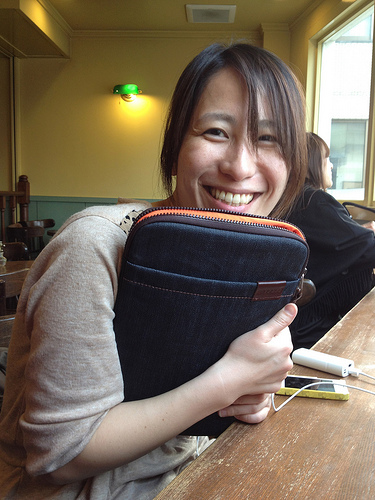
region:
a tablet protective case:
[120, 205, 310, 435]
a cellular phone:
[274, 374, 347, 399]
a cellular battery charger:
[292, 345, 355, 376]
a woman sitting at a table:
[2, 40, 307, 499]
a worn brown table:
[162, 285, 374, 497]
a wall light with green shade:
[109, 81, 140, 105]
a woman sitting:
[302, 130, 373, 287]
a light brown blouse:
[4, 200, 212, 499]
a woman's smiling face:
[159, 42, 303, 217]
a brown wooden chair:
[13, 213, 54, 252]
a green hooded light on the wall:
[108, 75, 142, 102]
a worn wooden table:
[161, 290, 372, 498]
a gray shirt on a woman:
[2, 196, 215, 498]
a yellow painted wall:
[0, 28, 315, 203]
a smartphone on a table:
[271, 370, 349, 400]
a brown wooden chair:
[4, 215, 60, 256]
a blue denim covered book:
[112, 207, 307, 407]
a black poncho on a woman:
[282, 183, 373, 312]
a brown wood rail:
[1, 167, 32, 233]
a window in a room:
[306, 1, 373, 208]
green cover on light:
[105, 79, 138, 97]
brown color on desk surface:
[252, 442, 339, 473]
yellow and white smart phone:
[291, 371, 355, 401]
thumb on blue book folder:
[250, 297, 300, 337]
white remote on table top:
[296, 342, 345, 373]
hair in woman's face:
[223, 50, 303, 156]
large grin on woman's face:
[194, 176, 274, 215]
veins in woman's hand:
[252, 348, 284, 384]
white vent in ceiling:
[168, 1, 261, 27]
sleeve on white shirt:
[27, 411, 102, 454]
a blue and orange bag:
[113, 200, 301, 435]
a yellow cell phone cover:
[276, 373, 352, 401]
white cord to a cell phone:
[272, 344, 374, 409]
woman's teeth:
[200, 179, 263, 215]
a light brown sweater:
[2, 191, 275, 497]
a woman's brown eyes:
[188, 116, 290, 151]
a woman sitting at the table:
[287, 133, 372, 284]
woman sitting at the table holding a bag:
[33, 46, 346, 497]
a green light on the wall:
[108, 76, 151, 109]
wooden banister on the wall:
[0, 171, 36, 227]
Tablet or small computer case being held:
[117, 199, 306, 430]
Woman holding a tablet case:
[18, 40, 300, 498]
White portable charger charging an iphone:
[263, 333, 373, 413]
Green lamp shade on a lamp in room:
[102, 76, 150, 112]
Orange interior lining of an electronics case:
[134, 208, 311, 234]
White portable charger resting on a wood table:
[289, 346, 360, 375]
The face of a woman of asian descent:
[139, 37, 316, 239]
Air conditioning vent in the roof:
[184, 3, 237, 25]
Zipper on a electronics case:
[296, 272, 307, 294]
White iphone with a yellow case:
[275, 374, 350, 402]